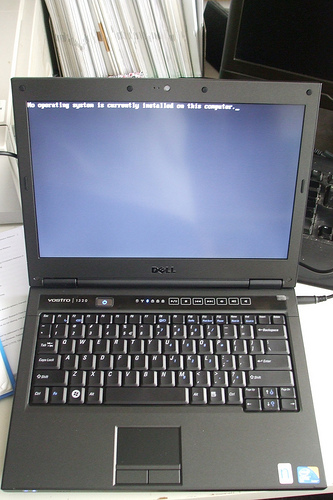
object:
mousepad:
[116, 427, 181, 466]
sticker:
[277, 461, 294, 486]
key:
[247, 369, 294, 385]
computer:
[0, 72, 327, 492]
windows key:
[68, 385, 85, 404]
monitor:
[25, 101, 305, 258]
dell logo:
[151, 265, 176, 274]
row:
[41, 314, 285, 323]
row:
[39, 325, 286, 339]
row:
[37, 336, 290, 355]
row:
[37, 354, 292, 372]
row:
[35, 368, 296, 389]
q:
[62, 339, 67, 345]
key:
[59, 337, 77, 355]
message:
[22, 98, 242, 114]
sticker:
[294, 465, 322, 485]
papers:
[0, 223, 31, 394]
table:
[0, 205, 333, 499]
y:
[147, 339, 153, 345]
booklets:
[44, 0, 65, 77]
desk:
[0, 0, 332, 499]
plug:
[296, 293, 332, 306]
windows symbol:
[297, 463, 320, 486]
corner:
[300, 79, 324, 107]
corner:
[5, 71, 28, 100]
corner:
[294, 460, 328, 499]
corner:
[0, 469, 23, 491]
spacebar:
[105, 387, 190, 404]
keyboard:
[30, 305, 297, 410]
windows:
[67, 386, 86, 405]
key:
[128, 339, 146, 353]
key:
[144, 338, 163, 355]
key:
[228, 371, 247, 388]